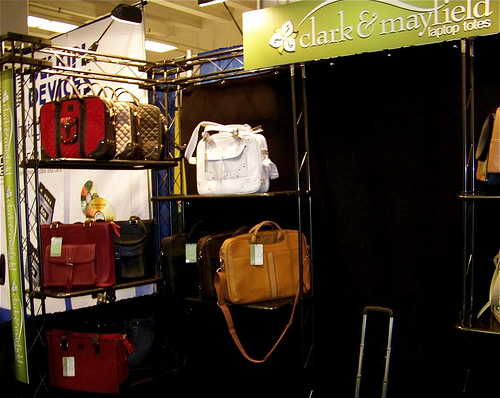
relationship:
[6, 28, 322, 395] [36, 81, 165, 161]
hanging shelves of bags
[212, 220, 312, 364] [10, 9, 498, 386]
bag in a store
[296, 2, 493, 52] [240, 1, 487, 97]
letters are in a sign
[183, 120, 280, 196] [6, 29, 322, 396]
bag is on display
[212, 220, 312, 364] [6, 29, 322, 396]
bag is on display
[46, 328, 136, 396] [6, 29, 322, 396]
bag is on display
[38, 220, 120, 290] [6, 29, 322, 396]
bag is on display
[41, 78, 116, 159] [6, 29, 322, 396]
bag is on display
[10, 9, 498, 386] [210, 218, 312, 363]
store sells bag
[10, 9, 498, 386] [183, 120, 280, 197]
store sells bag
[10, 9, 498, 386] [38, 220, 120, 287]
store sells bag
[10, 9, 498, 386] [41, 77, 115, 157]
store sells bag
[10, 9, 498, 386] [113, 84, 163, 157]
store sells bag